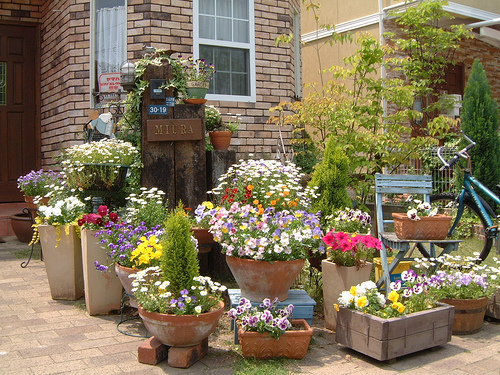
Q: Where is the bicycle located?
A: Right side.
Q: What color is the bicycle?
A: Blue.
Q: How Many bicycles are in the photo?
A: One.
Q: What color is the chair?
A: Light blue.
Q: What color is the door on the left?
A: Brown.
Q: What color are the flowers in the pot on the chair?
A: White.